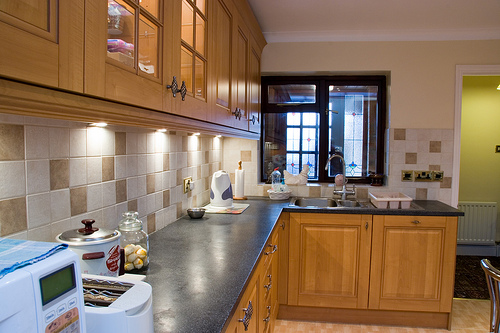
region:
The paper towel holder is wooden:
[225, 150, 261, 210]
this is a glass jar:
[115, 197, 152, 270]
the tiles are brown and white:
[382, 109, 459, 175]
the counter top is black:
[165, 195, 242, 310]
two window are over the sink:
[230, 65, 402, 201]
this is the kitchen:
[128, 21, 470, 322]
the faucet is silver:
[305, 130, 355, 201]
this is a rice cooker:
[53, 197, 140, 280]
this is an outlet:
[164, 167, 203, 200]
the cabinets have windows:
[85, 0, 214, 112]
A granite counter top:
[167, 220, 252, 298]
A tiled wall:
[23, 143, 173, 195]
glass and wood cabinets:
[68, 20, 251, 60]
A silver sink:
[287, 185, 371, 220]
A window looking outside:
[265, 76, 377, 178]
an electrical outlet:
[173, 168, 198, 185]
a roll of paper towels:
[231, 152, 253, 198]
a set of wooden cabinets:
[288, 217, 443, 324]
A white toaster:
[81, 275, 156, 332]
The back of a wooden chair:
[483, 257, 498, 307]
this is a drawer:
[292, 215, 454, 310]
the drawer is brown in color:
[298, 226, 425, 294]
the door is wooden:
[296, 218, 414, 292]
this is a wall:
[396, 50, 456, 120]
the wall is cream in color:
[411, 58, 443, 90]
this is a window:
[266, 79, 370, 156]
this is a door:
[463, 71, 498, 227]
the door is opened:
[470, 101, 485, 143]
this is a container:
[122, 210, 145, 257]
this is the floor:
[460, 278, 480, 328]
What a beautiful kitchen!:
[81, 29, 480, 300]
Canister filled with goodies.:
[44, 198, 192, 285]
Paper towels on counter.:
[231, 161, 270, 216]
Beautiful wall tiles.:
[95, 131, 237, 211]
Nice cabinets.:
[283, 181, 400, 332]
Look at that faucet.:
[322, 150, 364, 219]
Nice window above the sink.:
[250, 61, 421, 222]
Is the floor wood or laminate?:
[470, 306, 478, 330]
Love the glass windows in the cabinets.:
[109, 3, 256, 105]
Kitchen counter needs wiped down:
[155, 233, 226, 330]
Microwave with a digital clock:
[3, 239, 83, 329]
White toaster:
[77, 271, 152, 328]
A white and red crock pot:
[52, 211, 119, 273]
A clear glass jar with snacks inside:
[113, 206, 150, 268]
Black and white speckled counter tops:
[157, 186, 281, 326]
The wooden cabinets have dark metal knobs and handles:
[229, 208, 466, 327]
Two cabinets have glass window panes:
[88, 0, 205, 111]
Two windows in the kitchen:
[261, 67, 390, 180]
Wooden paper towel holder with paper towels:
[226, 155, 256, 203]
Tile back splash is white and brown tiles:
[5, 123, 237, 243]